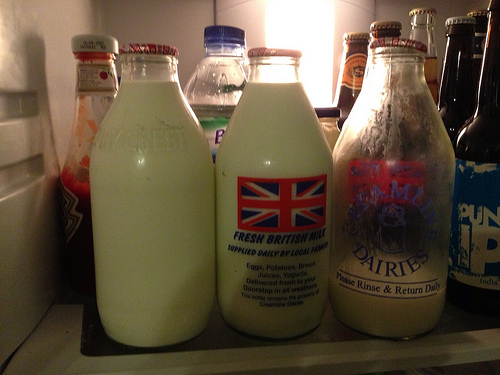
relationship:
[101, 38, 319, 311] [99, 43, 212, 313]
bottles of milk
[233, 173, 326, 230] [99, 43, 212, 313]
flag on milk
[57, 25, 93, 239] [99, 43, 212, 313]
ketchup behind milk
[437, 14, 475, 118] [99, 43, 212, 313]
bottle behind milk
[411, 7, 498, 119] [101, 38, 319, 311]
four beer bottles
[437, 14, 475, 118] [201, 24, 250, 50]
bottle with blue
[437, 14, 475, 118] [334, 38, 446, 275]
bottle almost empty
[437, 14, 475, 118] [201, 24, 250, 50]
bottle says blue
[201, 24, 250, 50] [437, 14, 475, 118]
blue on bottle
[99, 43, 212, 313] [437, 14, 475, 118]
milk on bottle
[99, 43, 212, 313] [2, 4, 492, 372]
milk in fridge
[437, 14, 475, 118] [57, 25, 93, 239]
bottle of ketchup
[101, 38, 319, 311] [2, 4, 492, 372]
bottles in fridge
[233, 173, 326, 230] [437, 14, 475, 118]
flag on bottle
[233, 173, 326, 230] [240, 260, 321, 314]
flag above letters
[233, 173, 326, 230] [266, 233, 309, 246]
flag for britain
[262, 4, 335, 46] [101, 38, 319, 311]
light behind bottles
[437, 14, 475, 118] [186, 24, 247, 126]
bottle of water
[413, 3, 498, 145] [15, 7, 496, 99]
beer in background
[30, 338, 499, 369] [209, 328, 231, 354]
shelf of glass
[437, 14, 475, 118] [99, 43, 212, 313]
bottle of milk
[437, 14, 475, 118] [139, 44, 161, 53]
bottle with red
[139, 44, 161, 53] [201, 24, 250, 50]
red white blue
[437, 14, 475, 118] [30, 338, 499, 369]
bottle on shelf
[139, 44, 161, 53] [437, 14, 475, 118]
red on bottle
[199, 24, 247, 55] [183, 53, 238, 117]
cap on container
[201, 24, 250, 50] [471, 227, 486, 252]
blue and white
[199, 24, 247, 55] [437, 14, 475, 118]
cap on bottle